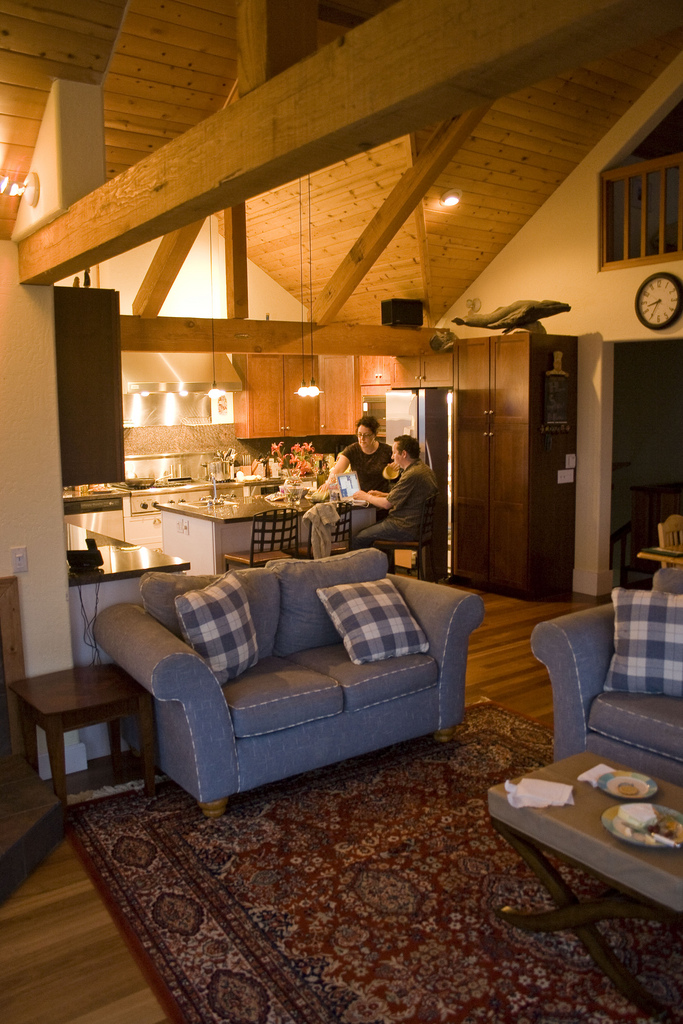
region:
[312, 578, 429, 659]
a checkered white and blue cushion on the couch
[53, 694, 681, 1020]
a red Persian rug on the wooden floor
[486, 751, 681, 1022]
a coffee table in front of couch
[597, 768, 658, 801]
a colorful plate on top of a coffee table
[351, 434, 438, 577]
a man sitting on a stool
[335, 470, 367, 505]
a laptop sitting on top of a kitchen island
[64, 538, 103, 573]
a landline phone on top of the counter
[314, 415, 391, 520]
a woman standing next to a man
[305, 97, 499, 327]
a beam of wood on the ceiling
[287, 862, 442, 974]
the rug is red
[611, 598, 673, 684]
a blue and white pillow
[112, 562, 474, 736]
the couch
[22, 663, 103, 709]
a small table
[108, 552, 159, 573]
a counter top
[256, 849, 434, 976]
a red rug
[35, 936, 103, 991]
a wooden floor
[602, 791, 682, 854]
a plate on the table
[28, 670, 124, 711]
the table is brown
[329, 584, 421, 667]
a pillow on the couch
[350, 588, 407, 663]
a blue and white pillow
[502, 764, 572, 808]
napkin on the table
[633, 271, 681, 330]
Clock hanging on wall.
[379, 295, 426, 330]
Speaker sitting on top of beam.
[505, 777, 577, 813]
Napkin on coffee table.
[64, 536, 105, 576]
Phone on kitchen counter.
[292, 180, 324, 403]
Light hanging from ceiling.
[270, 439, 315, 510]
Bouquet of flowers on kitchen island.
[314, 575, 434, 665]
Pillow on couch.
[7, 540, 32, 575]
Light switch on wall.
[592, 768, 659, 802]
Plate on coffee table.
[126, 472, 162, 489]
Skillet on top of stove.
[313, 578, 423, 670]
blue and white plaid pillow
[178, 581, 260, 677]
blue and white plaid pillow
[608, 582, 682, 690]
blue and white plaid pillow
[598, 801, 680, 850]
large blue yellow and white dish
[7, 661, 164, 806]
small brown side table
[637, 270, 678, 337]
Clock on the wall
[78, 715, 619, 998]
Red carpet on the floor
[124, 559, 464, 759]
An empty blue couch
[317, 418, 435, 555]
Two people sitting at table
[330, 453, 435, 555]
A man using a laptop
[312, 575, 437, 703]
A blue and white pillow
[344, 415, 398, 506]
Brunette woman wearing glasses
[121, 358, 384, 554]
Lights on in the kitchen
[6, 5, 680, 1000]
Beautifully decorated log house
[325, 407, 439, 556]
A couple in the kitchen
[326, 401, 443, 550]
Middle aged couple in the kitchen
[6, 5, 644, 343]
Wooden truss and beams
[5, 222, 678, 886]
Living and kitchen area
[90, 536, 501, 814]
Grey loveseat with pillows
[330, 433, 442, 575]
A man working on the laptop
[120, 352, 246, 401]
Stainless steel range hood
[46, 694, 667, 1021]
Maroon area rug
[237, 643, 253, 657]
A white square on a pillow.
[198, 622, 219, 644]
A white square on a pillow.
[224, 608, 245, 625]
A white square on a pillow.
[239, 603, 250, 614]
A white square on a pillow.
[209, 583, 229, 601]
A white square on a pillow.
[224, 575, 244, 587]
A white square on a pillow.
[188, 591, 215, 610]
A white square on a pillow.